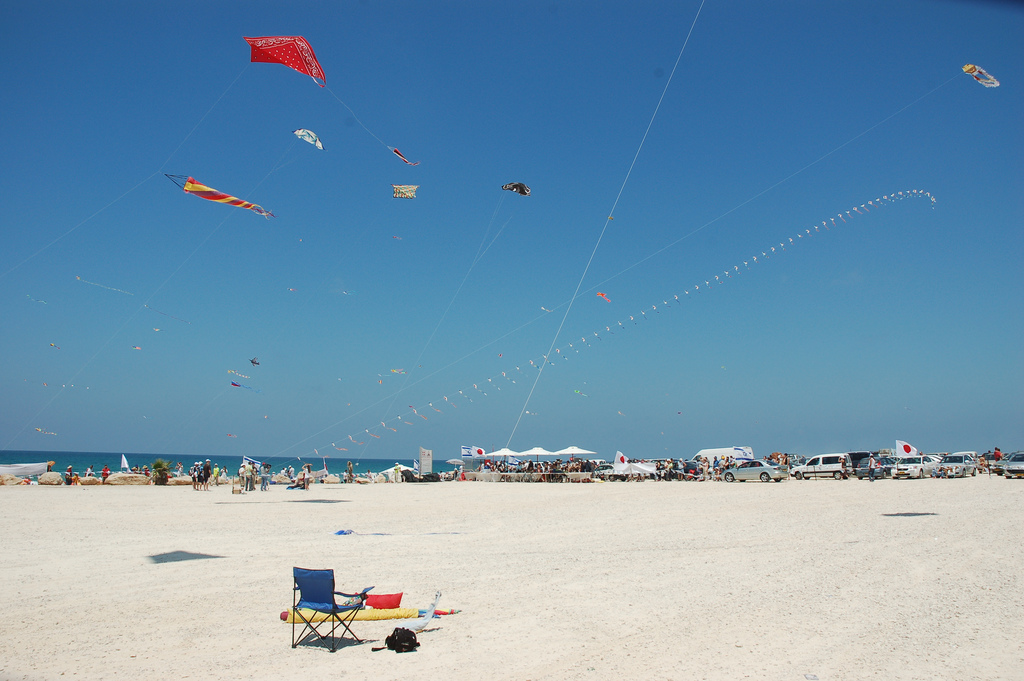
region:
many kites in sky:
[96, 21, 499, 291]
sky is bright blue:
[784, 17, 953, 192]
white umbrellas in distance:
[452, 438, 620, 481]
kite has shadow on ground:
[134, 536, 249, 572]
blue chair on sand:
[298, 561, 390, 650]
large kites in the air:
[141, 20, 579, 292]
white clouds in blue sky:
[640, 96, 689, 151]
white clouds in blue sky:
[720, 311, 810, 376]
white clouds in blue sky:
[455, 315, 531, 372]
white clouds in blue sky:
[142, 315, 210, 357]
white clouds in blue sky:
[22, 226, 109, 300]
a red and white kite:
[228, 22, 337, 100]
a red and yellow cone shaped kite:
[152, 164, 283, 228]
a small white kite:
[284, 120, 326, 160]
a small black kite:
[490, 170, 538, 206]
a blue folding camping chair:
[283, 559, 373, 661]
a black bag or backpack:
[372, 620, 430, 662]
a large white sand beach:
[0, 471, 1022, 674]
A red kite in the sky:
[231, 26, 326, 81]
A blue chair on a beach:
[286, 563, 364, 656]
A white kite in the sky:
[295, 124, 325, 147]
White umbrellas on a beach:
[488, 440, 590, 457]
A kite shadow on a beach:
[149, 544, 225, 565]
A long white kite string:
[501, 0, 705, 441]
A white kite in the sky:
[962, 62, 1002, 92]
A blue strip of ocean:
[4, 448, 466, 478]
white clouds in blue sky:
[57, 57, 124, 115]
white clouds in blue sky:
[503, 300, 573, 370]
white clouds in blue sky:
[829, 282, 913, 321]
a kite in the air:
[134, 171, 330, 279]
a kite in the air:
[295, 98, 324, 165]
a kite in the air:
[383, 186, 418, 215]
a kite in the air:
[500, 180, 538, 209]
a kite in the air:
[371, 118, 406, 167]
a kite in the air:
[210, 1, 347, 103]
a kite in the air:
[942, 48, 1006, 103]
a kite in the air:
[471, 165, 535, 223]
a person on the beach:
[236, 452, 265, 484]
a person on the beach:
[576, 434, 590, 472]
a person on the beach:
[541, 446, 552, 469]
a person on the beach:
[289, 472, 309, 492]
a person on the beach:
[143, 443, 160, 510]